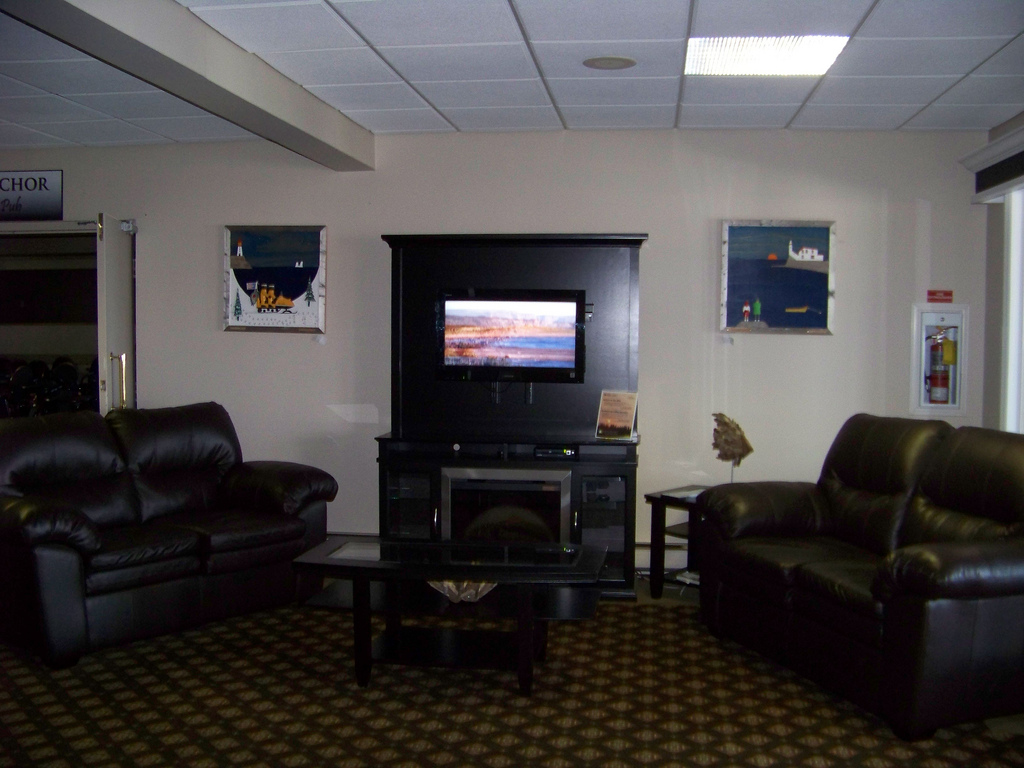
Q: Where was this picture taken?
A: Living room.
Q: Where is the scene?
A: In a den.